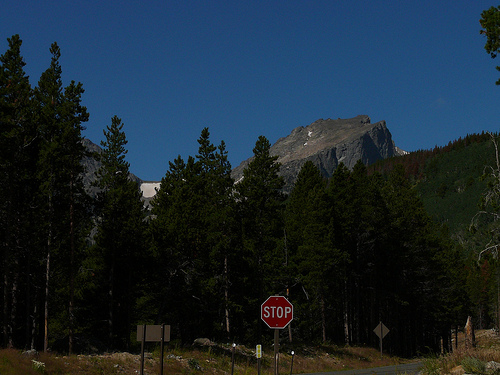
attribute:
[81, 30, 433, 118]
sky — blue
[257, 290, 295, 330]
stop sign — dark red, white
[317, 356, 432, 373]
road — empty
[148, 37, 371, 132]
sky — dark blue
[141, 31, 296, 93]
clouds — white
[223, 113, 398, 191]
rock — grey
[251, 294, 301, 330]
sign — shaped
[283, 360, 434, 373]
road — gray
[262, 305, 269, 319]
letter — white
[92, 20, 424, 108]
sky — blue 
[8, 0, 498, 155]
sky — blue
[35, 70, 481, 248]
pine trees — green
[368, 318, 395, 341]
sign — diamond shaped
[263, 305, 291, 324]
letters — white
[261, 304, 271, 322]
s — letter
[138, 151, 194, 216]
clouds — white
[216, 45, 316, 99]
cloud — white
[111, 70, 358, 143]
sky — blue